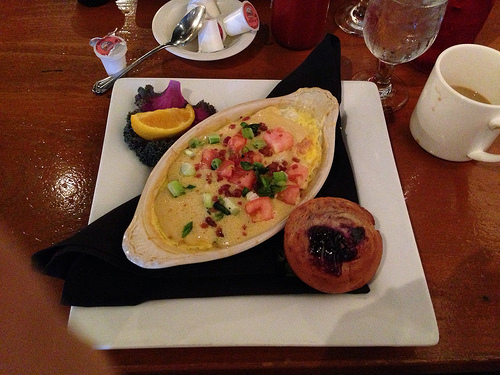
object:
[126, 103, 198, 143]
orange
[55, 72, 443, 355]
plate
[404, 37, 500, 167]
coffee cup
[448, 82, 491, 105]
coffee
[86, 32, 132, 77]
packet of creamer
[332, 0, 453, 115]
glass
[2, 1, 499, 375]
table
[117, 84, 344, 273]
meal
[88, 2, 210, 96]
napkin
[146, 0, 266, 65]
bowl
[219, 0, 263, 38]
creamer packets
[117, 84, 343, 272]
dish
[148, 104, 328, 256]
food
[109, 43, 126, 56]
milk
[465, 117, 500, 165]
handle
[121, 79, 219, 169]
garnish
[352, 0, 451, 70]
water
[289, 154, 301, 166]
green onions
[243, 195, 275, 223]
tomato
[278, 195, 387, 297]
pastry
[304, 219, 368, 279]
jam